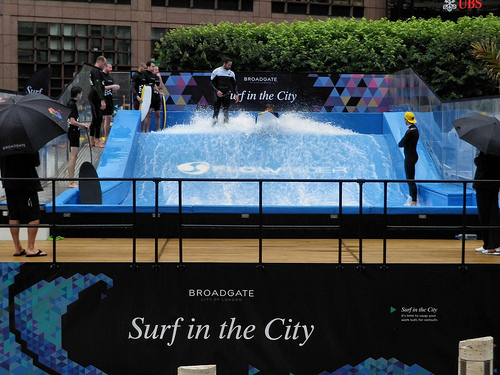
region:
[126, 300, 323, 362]
the text is white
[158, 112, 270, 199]
the water is blue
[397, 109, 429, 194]
the person is standing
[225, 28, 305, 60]
the bushes are green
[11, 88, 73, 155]
the umbrella is black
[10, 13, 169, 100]
the building is brown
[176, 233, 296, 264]
the floor is brown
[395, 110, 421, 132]
the cap is yellow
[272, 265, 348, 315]
the banner is black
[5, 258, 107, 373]
the design is blue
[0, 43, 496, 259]
People are standing around a blue object filled with water.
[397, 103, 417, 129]
A person is wearing a yellow cap.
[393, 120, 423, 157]
A person is wearing a black top.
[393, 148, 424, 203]
A person is wearing black pants.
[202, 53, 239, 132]
A man is standing in some water.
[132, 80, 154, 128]
A person is holding a white and yellow object.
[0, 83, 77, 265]
A person is holding a black umbrella with a yellow, red, and blue logo on it.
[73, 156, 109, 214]
A round object is sitting on it's side.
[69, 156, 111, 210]
A round object's color is black.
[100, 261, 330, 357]
A " Surf in the City " sign is in the foreground.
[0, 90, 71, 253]
a person with an open umbrella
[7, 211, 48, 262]
the person is wearing sandals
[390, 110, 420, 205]
a boy is wearing a cap backwards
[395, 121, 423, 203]
the boy is wearing black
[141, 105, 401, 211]
a man made water fall ride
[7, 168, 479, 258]
a rail at the end of walkway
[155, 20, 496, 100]
a green hedge behind the water ride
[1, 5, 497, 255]
the water ride is in front of a building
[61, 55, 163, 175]
people in line waiting to ride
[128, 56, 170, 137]
riders are holding their boards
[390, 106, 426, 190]
man in yellow hat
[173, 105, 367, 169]
man made wave for surfing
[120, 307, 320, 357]
white words on black background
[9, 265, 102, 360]
digital art of wave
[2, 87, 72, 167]
black umbrella over man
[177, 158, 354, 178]
white logo under water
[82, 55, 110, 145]
man wearing black wetsuit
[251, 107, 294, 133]
tip of surfboard in water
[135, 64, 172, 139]
people standing with surfboards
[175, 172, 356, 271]
black rail behind stage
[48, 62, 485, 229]
"Surf in the City" pool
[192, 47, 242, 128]
man wearing wetsuit in pool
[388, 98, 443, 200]
man wearing yellow cap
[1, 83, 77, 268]
person holding black umbrella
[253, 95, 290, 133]
person lying on surfboard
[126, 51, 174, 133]
man holding surf board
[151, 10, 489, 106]
hedge bush behind surf pool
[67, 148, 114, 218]
surf board standing in pool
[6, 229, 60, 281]
person wearing flip flops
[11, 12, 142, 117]
wall of windows on building